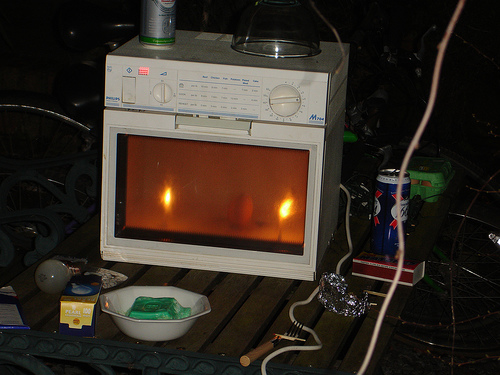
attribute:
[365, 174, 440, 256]
can — soda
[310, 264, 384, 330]
aluminum — crumpled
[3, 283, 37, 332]
paper — blue, white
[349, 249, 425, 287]
box — matches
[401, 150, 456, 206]
box — green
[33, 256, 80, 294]
light bulb — glass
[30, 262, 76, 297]
light bulb — incandescent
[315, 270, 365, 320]
ball — foil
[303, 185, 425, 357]
cord — power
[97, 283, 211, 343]
bowl — white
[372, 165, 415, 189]
top soda — can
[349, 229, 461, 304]
box — red, white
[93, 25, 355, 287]
microwave oven — on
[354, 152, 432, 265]
drink can — blue, white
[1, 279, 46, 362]
wrapper — blue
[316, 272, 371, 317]
foil — piece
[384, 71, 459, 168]
wire — white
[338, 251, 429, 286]
box — red, white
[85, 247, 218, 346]
bowl — white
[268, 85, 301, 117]
dial — white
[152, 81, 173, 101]
dial — white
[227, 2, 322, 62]
bowl — glass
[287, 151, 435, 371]
slat — wood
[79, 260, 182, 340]
slat — wooden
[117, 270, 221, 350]
slat — wooden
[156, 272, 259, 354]
slat — wooden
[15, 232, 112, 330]
slat — wooden